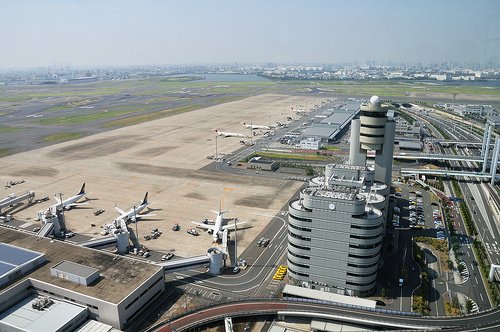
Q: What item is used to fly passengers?
A: A airplane.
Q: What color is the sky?
A: Blue.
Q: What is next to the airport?
A: Roads/traffic.